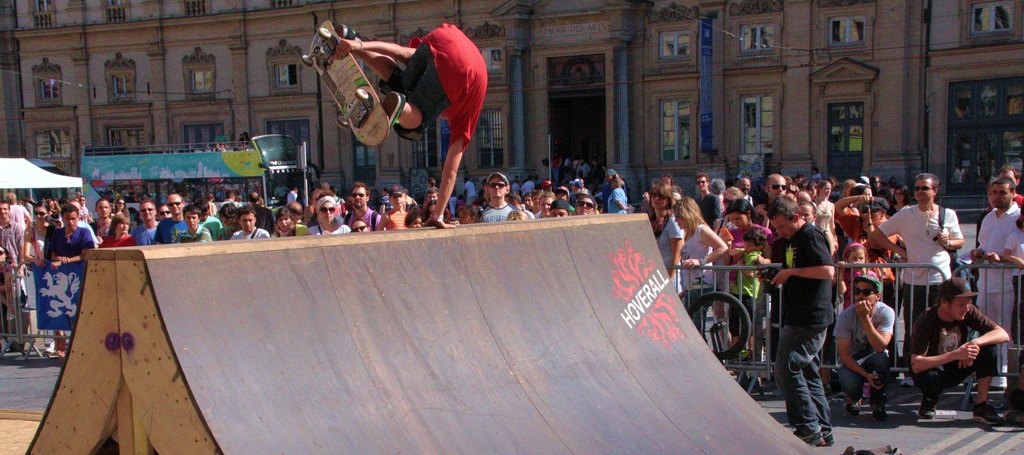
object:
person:
[299, 20, 488, 230]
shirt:
[410, 21, 487, 152]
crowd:
[0, 162, 1021, 447]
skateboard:
[299, 18, 392, 147]